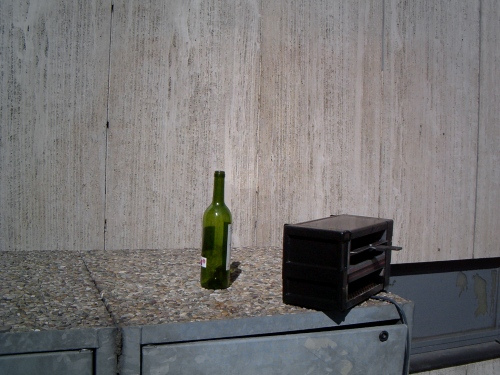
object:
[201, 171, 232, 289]
bottle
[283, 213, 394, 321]
black object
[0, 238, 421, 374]
counter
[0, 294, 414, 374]
cabinet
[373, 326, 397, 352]
lock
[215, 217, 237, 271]
label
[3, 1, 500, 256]
wall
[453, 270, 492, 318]
paint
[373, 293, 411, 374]
cord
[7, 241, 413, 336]
stone tops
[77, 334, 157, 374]
hinges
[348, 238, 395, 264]
tray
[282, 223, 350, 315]
back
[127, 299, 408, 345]
top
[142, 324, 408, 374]
cabinet door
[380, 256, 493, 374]
divider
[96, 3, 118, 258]
line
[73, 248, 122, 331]
crack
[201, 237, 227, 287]
wine